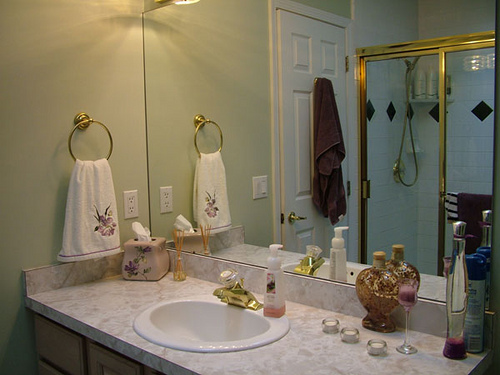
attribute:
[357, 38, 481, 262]
shower — in the background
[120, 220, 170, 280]
dispenser — toilet paper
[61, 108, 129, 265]
towel — in holder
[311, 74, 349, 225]
towel — on a door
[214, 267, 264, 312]
brass faucet — on a sink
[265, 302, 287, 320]
hand soap — in a bottle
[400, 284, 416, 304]
candle — in glass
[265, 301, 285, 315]
hand soap — in a plastic bottle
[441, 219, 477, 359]
long bottle — of perfume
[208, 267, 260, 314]
faucet fixture — white and gold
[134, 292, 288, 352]
white sink — with gold fixture, in a bathroom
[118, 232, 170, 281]
tissue box — floral, container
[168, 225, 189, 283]
aroma oil — with sticks sticking out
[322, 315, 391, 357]
small candles — on a counter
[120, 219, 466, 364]
items — on the counter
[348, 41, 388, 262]
frame — gold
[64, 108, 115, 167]
towel rack — gold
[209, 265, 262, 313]
bathroom faucet — gold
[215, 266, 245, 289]
handle — clear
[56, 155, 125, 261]
towel — white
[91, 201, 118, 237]
flower — purple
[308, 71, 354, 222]
towel — purple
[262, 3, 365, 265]
door — white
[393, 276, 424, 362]
glass — tall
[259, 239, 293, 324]
bottle — almost empty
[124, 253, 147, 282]
flower — purple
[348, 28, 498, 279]
shower door — doubled, glass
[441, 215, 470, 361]
bottle — tall, decorative